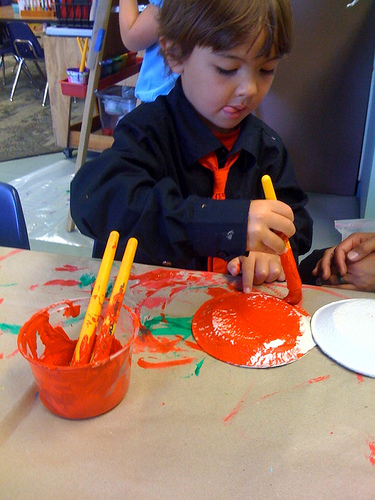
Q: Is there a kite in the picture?
A: No, there are no kites.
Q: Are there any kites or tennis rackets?
A: No, there are no kites or tennis rackets.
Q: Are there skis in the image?
A: No, there are no skis.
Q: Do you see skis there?
A: No, there are no skis.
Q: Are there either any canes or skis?
A: No, there are no skis or canes.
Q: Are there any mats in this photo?
A: No, there are no mats.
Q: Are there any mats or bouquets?
A: No, there are no mats or bouquets.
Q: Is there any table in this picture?
A: Yes, there is a table.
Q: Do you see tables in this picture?
A: Yes, there is a table.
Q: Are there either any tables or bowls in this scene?
A: Yes, there is a table.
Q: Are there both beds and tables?
A: No, there is a table but no beds.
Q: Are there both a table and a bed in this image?
A: No, there is a table but no beds.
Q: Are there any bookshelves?
A: No, there are no bookshelves.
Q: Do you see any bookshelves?
A: No, there are no bookshelves.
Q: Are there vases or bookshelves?
A: No, there are no bookshelves or vases.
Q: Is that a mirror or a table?
A: That is a table.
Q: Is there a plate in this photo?
A: Yes, there is a plate.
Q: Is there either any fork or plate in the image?
A: Yes, there is a plate.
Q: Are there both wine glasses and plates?
A: No, there is a plate but no wine glasses.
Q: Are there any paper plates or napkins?
A: Yes, there is a paper plate.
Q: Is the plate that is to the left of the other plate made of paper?
A: Yes, the plate is made of paper.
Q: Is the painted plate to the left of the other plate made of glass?
A: No, the plate is made of paper.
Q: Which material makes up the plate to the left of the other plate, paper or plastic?
A: The plate is made of paper.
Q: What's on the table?
A: The plate is on the table.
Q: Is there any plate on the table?
A: Yes, there is a plate on the table.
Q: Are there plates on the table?
A: Yes, there is a plate on the table.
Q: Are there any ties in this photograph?
A: Yes, there is a tie.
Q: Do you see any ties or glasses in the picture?
A: Yes, there is a tie.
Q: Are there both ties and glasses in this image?
A: No, there is a tie but no glasses.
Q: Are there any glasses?
A: No, there are no glasses.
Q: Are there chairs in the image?
A: Yes, there is a chair.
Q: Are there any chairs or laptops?
A: Yes, there is a chair.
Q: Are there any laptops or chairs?
A: Yes, there is a chair.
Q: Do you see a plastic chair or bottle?
A: Yes, there is a plastic chair.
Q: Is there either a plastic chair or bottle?
A: Yes, there is a plastic chair.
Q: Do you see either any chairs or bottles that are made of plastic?
A: Yes, the chair is made of plastic.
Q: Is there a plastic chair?
A: Yes, there is a chair that is made of plastic.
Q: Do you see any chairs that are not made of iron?
A: Yes, there is a chair that is made of plastic.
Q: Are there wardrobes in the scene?
A: No, there are no wardrobes.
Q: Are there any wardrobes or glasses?
A: No, there are no wardrobes or glasses.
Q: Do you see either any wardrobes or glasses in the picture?
A: No, there are no wardrobes or glasses.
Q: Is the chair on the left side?
A: Yes, the chair is on the left of the image.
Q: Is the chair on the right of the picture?
A: No, the chair is on the left of the image.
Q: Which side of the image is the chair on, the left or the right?
A: The chair is on the left of the image.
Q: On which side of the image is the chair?
A: The chair is on the left of the image.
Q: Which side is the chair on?
A: The chair is on the left of the image.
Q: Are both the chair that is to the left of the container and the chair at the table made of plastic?
A: Yes, both the chair and the chair are made of plastic.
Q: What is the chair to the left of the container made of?
A: The chair is made of plastic.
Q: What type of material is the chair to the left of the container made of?
A: The chair is made of plastic.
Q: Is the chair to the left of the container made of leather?
A: No, the chair is made of plastic.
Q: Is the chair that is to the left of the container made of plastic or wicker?
A: The chair is made of plastic.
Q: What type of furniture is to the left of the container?
A: The piece of furniture is a chair.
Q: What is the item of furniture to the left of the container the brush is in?
A: The piece of furniture is a chair.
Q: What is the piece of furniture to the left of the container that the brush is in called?
A: The piece of furniture is a chair.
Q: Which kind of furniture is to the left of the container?
A: The piece of furniture is a chair.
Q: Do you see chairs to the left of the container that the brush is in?
A: Yes, there is a chair to the left of the container.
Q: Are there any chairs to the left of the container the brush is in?
A: Yes, there is a chair to the left of the container.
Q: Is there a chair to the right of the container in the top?
A: No, the chair is to the left of the container.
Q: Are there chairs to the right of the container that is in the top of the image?
A: No, the chair is to the left of the container.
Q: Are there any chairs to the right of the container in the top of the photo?
A: No, the chair is to the left of the container.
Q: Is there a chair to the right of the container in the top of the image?
A: No, the chair is to the left of the container.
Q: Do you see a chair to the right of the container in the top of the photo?
A: No, the chair is to the left of the container.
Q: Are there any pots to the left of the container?
A: No, there is a chair to the left of the container.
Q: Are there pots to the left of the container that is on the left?
A: No, there is a chair to the left of the container.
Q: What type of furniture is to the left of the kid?
A: The piece of furniture is a chair.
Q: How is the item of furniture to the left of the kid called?
A: The piece of furniture is a chair.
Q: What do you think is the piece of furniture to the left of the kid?
A: The piece of furniture is a chair.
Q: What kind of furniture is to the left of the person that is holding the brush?
A: The piece of furniture is a chair.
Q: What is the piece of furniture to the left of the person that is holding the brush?
A: The piece of furniture is a chair.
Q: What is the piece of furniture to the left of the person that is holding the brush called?
A: The piece of furniture is a chair.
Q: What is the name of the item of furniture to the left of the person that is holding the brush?
A: The piece of furniture is a chair.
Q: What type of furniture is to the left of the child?
A: The piece of furniture is a chair.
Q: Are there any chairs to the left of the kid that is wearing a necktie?
A: Yes, there is a chair to the left of the kid.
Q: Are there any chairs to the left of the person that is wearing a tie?
A: Yes, there is a chair to the left of the kid.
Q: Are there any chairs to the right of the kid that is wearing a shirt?
A: No, the chair is to the left of the kid.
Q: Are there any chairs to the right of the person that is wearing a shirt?
A: No, the chair is to the left of the kid.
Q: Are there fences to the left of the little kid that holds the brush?
A: No, there is a chair to the left of the child.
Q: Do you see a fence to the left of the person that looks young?
A: No, there is a chair to the left of the child.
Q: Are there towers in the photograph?
A: No, there are no towers.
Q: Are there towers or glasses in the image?
A: No, there are no towers or glasses.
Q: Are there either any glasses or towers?
A: No, there are no towers or glasses.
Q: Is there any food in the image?
A: No, there is no food.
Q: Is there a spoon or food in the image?
A: No, there are no food or spoons.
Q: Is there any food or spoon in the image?
A: No, there are no food or spoons.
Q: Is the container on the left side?
A: Yes, the container is on the left of the image.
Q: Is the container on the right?
A: No, the container is on the left of the image.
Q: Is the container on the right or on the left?
A: The container is on the left of the image.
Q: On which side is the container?
A: The container is on the left of the image.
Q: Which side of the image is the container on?
A: The container is on the left of the image.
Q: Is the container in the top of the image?
A: Yes, the container is in the top of the image.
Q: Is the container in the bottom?
A: No, the container is in the top of the image.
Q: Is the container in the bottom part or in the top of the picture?
A: The container is in the top of the image.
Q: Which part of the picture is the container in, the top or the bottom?
A: The container is in the top of the image.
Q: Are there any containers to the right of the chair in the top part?
A: Yes, there is a container to the right of the chair.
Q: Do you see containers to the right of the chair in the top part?
A: Yes, there is a container to the right of the chair.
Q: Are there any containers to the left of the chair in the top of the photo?
A: No, the container is to the right of the chair.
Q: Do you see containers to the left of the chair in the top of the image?
A: No, the container is to the right of the chair.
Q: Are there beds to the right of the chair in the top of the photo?
A: No, there is a container to the right of the chair.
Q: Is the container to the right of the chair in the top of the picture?
A: Yes, the container is to the right of the chair.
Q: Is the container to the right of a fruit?
A: No, the container is to the right of the chair.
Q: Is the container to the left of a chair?
A: No, the container is to the right of a chair.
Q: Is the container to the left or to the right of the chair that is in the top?
A: The container is to the right of the chair.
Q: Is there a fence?
A: No, there are no fences.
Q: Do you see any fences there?
A: No, there are no fences.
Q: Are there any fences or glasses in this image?
A: No, there are no fences or glasses.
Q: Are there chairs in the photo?
A: Yes, there is a chair.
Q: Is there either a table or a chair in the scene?
A: Yes, there is a chair.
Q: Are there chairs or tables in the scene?
A: Yes, there is a chair.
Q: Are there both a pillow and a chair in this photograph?
A: No, there is a chair but no pillows.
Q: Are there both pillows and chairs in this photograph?
A: No, there is a chair but no pillows.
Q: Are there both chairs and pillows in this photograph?
A: No, there is a chair but no pillows.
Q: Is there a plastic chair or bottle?
A: Yes, there is a plastic chair.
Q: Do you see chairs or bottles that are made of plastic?
A: Yes, the chair is made of plastic.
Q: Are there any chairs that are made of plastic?
A: Yes, there is a chair that is made of plastic.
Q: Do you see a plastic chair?
A: Yes, there is a chair that is made of plastic.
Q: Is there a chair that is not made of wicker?
A: Yes, there is a chair that is made of plastic.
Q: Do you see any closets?
A: No, there are no closets.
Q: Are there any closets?
A: No, there are no closets.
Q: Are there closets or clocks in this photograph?
A: No, there are no closets or clocks.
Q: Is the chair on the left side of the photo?
A: Yes, the chair is on the left of the image.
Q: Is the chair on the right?
A: No, the chair is on the left of the image.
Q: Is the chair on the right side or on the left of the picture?
A: The chair is on the left of the image.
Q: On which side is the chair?
A: The chair is on the left of the image.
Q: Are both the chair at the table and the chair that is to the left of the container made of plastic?
A: Yes, both the chair and the chair are made of plastic.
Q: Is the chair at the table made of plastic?
A: Yes, the chair is made of plastic.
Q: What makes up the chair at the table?
A: The chair is made of plastic.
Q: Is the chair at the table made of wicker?
A: No, the chair is made of plastic.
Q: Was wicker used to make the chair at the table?
A: No, the chair is made of plastic.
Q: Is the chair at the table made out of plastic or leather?
A: The chair is made of plastic.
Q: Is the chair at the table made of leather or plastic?
A: The chair is made of plastic.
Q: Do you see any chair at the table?
A: Yes, there is a chair at the table.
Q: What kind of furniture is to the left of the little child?
A: The piece of furniture is a chair.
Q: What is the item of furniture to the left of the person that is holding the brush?
A: The piece of furniture is a chair.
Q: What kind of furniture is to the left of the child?
A: The piece of furniture is a chair.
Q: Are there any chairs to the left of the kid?
A: Yes, there is a chair to the left of the kid.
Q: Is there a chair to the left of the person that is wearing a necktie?
A: Yes, there is a chair to the left of the kid.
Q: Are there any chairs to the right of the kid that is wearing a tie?
A: No, the chair is to the left of the child.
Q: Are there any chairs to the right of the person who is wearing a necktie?
A: No, the chair is to the left of the child.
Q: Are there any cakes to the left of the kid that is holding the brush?
A: No, there is a chair to the left of the kid.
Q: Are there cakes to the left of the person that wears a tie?
A: No, there is a chair to the left of the kid.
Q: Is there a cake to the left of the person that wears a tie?
A: No, there is a chair to the left of the kid.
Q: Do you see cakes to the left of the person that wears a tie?
A: No, there is a chair to the left of the kid.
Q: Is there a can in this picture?
A: No, there are no cans.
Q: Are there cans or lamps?
A: No, there are no cans or lamps.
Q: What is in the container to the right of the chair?
A: The brush is in the container.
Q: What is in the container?
A: The brush is in the container.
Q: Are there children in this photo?
A: Yes, there is a child.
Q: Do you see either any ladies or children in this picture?
A: Yes, there is a child.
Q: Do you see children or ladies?
A: Yes, there is a child.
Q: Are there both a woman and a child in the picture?
A: No, there is a child but no women.